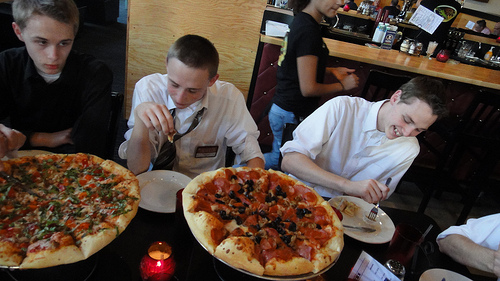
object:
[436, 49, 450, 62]
candle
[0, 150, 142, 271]
pie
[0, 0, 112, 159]
boy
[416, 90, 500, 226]
stool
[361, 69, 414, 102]
stool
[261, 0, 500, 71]
shelve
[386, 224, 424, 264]
glass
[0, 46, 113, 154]
tee shirt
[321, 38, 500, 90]
counter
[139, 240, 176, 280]
candle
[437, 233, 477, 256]
elbow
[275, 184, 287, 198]
olives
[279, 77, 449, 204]
boy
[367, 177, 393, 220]
fork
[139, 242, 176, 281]
red glass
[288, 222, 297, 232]
black olives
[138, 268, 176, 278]
candle holder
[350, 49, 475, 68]
grey building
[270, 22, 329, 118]
woman's shirt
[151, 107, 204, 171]
tie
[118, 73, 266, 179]
shirt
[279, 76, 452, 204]
shirt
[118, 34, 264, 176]
boy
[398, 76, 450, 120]
hair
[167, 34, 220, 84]
hair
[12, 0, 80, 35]
hair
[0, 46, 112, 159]
black shirt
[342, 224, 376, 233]
utensil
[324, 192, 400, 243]
plate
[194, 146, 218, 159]
name tag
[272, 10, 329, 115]
shirt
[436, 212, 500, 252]
shirt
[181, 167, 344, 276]
pizza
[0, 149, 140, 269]
pizza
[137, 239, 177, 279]
holder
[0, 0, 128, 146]
area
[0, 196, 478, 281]
table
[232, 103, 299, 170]
jeans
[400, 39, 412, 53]
toothpicks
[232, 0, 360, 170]
person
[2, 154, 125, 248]
toppings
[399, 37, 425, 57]
condiments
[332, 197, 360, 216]
food